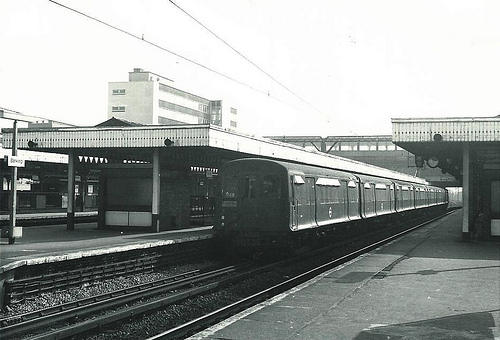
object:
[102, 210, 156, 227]
bench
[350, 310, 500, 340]
casting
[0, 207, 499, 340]
ground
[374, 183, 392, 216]
windows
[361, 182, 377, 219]
windows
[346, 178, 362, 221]
windows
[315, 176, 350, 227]
windows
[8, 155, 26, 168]
sign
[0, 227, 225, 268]
platform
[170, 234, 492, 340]
train platform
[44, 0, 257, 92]
lines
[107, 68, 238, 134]
building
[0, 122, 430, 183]
roof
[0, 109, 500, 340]
station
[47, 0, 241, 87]
powerlines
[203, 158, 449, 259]
train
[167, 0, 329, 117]
cables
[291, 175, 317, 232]
windows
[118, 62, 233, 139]
rise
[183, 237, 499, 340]
platform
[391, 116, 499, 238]
platform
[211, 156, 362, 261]
front car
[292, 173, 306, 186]
awning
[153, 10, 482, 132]
sky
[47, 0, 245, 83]
wires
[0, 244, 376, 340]
tracks ground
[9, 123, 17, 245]
box/pole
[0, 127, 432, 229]
covered area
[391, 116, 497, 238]
covered area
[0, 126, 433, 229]
depot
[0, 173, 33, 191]
box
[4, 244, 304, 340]
tracks